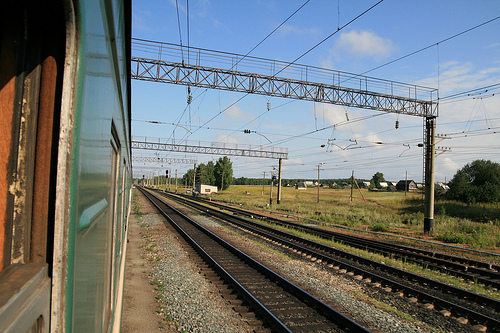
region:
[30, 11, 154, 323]
green light rail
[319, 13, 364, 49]
white clouds in blue sky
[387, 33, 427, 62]
white clouds in blue sky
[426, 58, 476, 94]
white clouds in blue sky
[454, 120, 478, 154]
white clouds in blue sky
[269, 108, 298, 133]
white clouds in blue sky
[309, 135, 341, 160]
white clouds in blue sky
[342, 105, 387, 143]
white clouds in blue sky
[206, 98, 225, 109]
white clouds in blue sky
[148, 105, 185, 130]
white clouds in blue sky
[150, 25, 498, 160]
power lines over tracks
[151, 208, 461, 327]
train tracks are black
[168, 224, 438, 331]
grey ballast between tracks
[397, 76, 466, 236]
grey poles near tracks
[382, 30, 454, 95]
blue and white sky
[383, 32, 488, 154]
white clouds in sky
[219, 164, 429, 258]
green grass between tracks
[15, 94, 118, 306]
side of train car is green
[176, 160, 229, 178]
green trees in distance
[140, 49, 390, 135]
metal bars over train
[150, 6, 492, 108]
power lines above a train track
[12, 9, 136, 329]
a green and brown train car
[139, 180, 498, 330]
a long set of train tracks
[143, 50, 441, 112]
metal scaffolding above a train track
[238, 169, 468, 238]
countryside next to train tracks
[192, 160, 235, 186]
green trees next to train tracks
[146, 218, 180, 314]
gravel lining the side of train tracks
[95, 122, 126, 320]
the window on a train car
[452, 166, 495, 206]
a tree growing in a field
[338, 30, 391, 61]
white puffy clouds in a blue sky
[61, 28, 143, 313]
green train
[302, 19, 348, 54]
white clouds in blue sky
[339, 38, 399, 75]
white clouds in blue sky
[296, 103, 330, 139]
white clouds in blue sky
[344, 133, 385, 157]
white clouds in blue sky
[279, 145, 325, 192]
white clouds in blue sky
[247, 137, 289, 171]
white clouds in blue sky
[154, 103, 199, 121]
white clouds in blue sky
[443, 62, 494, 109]
white clouds in blue sky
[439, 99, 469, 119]
white clouds in blue sky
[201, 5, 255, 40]
The sky is blue.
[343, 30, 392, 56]
The cloud is white.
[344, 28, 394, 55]
The cloud is in the sky.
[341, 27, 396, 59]
The cloud is small.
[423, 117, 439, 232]
The pole is made of metal.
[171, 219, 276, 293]
The train tracks are black.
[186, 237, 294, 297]
The train tracks are made of steel.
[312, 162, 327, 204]
The telephone pole is brown.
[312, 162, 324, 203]
The telephone pole is made of wood.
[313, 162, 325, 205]
The telephone pole is tall.